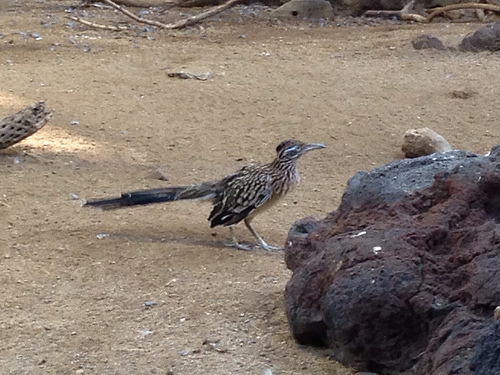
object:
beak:
[302, 143, 325, 150]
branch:
[63, 14, 126, 30]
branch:
[362, 4, 499, 23]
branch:
[104, 1, 236, 30]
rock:
[459, 21, 498, 53]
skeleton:
[0, 102, 50, 148]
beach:
[0, 0, 499, 373]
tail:
[84, 184, 215, 211]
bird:
[84, 140, 324, 252]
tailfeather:
[86, 184, 216, 205]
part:
[0, 223, 129, 317]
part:
[281, 238, 373, 321]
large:
[284, 145, 496, 373]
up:
[339, 148, 500, 208]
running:
[85, 140, 326, 250]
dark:
[342, 268, 430, 352]